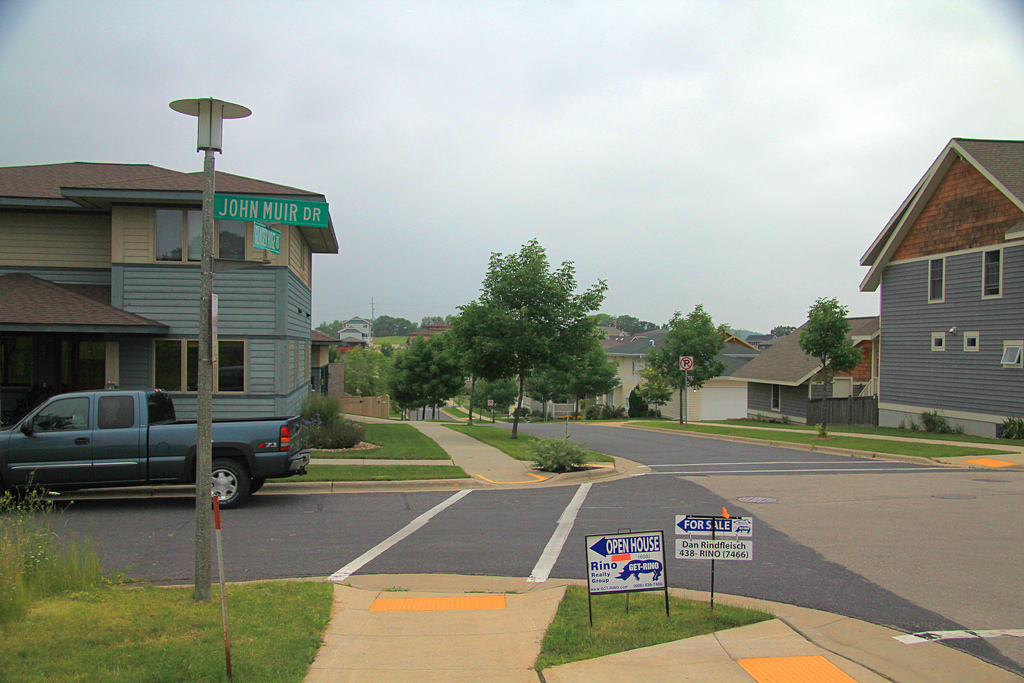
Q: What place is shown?
A: It is a road.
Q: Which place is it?
A: It is a road.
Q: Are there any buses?
A: No, there are no buses.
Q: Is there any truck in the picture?
A: Yes, there is a truck.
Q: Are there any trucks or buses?
A: Yes, there is a truck.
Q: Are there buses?
A: No, there are no buses.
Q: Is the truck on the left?
A: Yes, the truck is on the left of the image.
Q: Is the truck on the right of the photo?
A: No, the truck is on the left of the image.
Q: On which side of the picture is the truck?
A: The truck is on the left of the image.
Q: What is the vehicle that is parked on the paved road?
A: The vehicle is a truck.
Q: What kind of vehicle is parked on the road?
A: The vehicle is a truck.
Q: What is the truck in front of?
A: The truck is in front of the building.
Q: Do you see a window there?
A: Yes, there is a window.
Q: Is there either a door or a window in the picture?
A: Yes, there is a window.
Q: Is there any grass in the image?
A: Yes, there is grass.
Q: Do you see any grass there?
A: Yes, there is grass.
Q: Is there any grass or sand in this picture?
A: Yes, there is grass.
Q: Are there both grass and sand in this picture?
A: No, there is grass but no sand.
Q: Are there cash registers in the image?
A: No, there are no cash registers.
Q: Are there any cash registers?
A: No, there are no cash registers.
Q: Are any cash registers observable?
A: No, there are no cash registers.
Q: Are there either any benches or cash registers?
A: No, there are no cash registers or benches.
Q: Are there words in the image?
A: Yes, there are words.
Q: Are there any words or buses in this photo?
A: Yes, there are words.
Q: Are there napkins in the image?
A: No, there are no napkins.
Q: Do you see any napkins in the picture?
A: No, there are no napkins.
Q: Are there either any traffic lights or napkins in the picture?
A: No, there are no napkins or traffic lights.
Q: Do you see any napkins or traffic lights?
A: No, there are no napkins or traffic lights.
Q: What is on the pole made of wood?
A: The light post is on the pole.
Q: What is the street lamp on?
A: The street lamp is on the pole.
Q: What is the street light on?
A: The street lamp is on the pole.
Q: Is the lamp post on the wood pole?
A: Yes, the lamp post is on the pole.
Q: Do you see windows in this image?
A: Yes, there is a window.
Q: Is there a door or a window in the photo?
A: Yes, there is a window.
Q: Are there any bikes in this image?
A: No, there are no bikes.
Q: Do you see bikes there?
A: No, there are no bikes.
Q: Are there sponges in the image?
A: No, there are no sponges.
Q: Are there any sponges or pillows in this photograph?
A: No, there are no sponges or pillows.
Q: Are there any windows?
A: Yes, there is a window.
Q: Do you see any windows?
A: Yes, there is a window.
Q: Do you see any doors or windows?
A: Yes, there is a window.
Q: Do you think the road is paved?
A: Yes, the road is paved.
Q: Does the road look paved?
A: Yes, the road is paved.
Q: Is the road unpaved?
A: No, the road is paved.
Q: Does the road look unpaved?
A: No, the road is paved.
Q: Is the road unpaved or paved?
A: The road is paved.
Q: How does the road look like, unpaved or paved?
A: The road is paved.